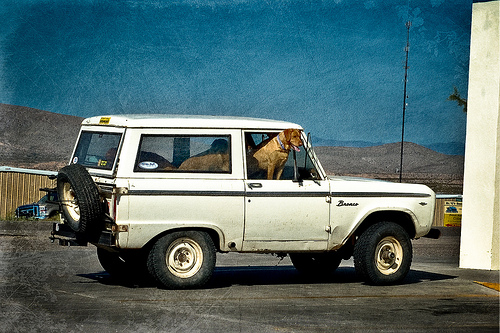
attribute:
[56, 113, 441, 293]
jeep — white, black, parked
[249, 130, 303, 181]
dog — tan, brown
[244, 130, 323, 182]
window — passenger window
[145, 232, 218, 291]
tire — black, dirty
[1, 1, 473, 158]
sky — blue, bright, clear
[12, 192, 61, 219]
truck — blue, white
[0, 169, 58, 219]
fence — brown, wooden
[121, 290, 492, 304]
line — yellow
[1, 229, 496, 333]
pavement — black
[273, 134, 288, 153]
collar — blue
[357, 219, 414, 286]
tire — black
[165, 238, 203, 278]
hubcap — white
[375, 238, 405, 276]
hubcap — white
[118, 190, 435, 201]
stripe — black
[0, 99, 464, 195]
mountain range — tan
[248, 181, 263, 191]
door — silver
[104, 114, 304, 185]
dogs — brown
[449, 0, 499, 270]
building — white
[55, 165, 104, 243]
tire — black, spare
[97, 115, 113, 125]
sticker — yellow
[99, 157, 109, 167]
sticker — yellow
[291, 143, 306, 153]
mouth — open